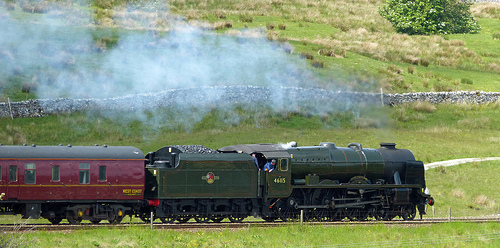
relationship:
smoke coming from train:
[9, 10, 381, 125] [5, 133, 436, 225]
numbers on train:
[270, 174, 289, 185] [5, 133, 436, 225]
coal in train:
[175, 133, 220, 158] [5, 133, 436, 225]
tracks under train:
[6, 221, 497, 224] [5, 133, 436, 225]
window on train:
[94, 158, 117, 191] [5, 133, 436, 225]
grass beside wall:
[16, 44, 493, 87] [4, 84, 497, 106]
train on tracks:
[5, 133, 436, 225] [6, 221, 497, 224]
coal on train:
[175, 133, 220, 158] [5, 133, 436, 225]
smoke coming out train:
[9, 10, 381, 125] [5, 133, 436, 225]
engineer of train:
[262, 157, 278, 170] [5, 133, 436, 225]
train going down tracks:
[5, 133, 436, 225] [6, 221, 497, 224]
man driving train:
[262, 157, 278, 170] [5, 133, 436, 225]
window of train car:
[94, 158, 117, 191] [1, 139, 151, 223]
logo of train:
[198, 168, 224, 187] [5, 133, 436, 225]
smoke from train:
[9, 10, 381, 125] [5, 133, 436, 225]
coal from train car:
[175, 133, 220, 158] [1, 139, 151, 223]